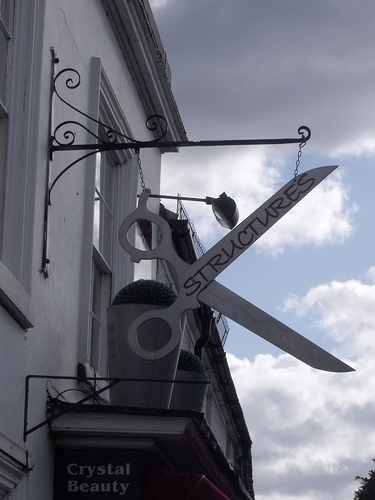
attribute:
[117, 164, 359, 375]
scissors — white, silver, hanging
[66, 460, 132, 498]
words — white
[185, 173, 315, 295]
font — black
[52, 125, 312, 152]
pole — black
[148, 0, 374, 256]
clouds — white, fluffy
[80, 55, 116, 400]
window — tall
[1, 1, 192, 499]
building — white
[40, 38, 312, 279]
sign hanger — black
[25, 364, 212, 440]
sign holder — metal, fancy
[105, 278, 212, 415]
two cups of slushies — big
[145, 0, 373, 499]
sky — blue